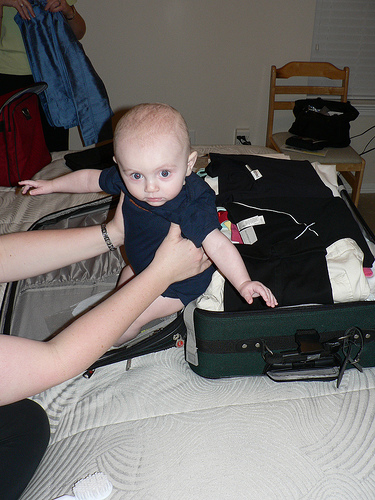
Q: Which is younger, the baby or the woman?
A: The baby is younger than the woman.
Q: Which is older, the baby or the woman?
A: The woman is older than the baby.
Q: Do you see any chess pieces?
A: No, there are no chess pieces.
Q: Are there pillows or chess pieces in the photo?
A: No, there are no chess pieces or pillows.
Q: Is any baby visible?
A: Yes, there is a baby.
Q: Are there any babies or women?
A: Yes, there is a baby.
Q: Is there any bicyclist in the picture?
A: No, there are no cyclists.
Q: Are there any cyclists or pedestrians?
A: No, there are no cyclists or pedestrians.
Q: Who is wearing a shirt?
A: The baby is wearing a shirt.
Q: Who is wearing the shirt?
A: The baby is wearing a shirt.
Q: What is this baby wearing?
A: The baby is wearing a shirt.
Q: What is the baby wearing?
A: The baby is wearing a shirt.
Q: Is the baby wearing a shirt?
A: Yes, the baby is wearing a shirt.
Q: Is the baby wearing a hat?
A: No, the baby is wearing a shirt.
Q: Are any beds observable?
A: Yes, there is a bed.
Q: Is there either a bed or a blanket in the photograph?
A: Yes, there is a bed.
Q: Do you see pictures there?
A: No, there are no pictures.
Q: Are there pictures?
A: No, there are no pictures.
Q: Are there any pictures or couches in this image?
A: No, there are no pictures or couches.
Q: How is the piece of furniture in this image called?
A: The piece of furniture is a bed.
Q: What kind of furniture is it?
A: The piece of furniture is a bed.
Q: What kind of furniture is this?
A: This is a bed.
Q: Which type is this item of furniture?
A: This is a bed.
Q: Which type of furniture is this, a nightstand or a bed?
A: This is a bed.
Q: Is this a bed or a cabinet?
A: This is a bed.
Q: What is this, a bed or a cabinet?
A: This is a bed.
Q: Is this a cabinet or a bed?
A: This is a bed.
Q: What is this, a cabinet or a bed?
A: This is a bed.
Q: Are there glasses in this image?
A: No, there are no glasses.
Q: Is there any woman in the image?
A: Yes, there is a woman.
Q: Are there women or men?
A: Yes, there is a woman.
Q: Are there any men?
A: No, there are no men.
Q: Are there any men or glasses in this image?
A: No, there are no men or glasses.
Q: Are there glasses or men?
A: No, there are no men or glasses.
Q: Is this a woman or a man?
A: This is a woman.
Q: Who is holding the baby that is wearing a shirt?
A: The woman is holding the baby.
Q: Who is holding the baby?
A: The woman is holding the baby.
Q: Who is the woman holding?
A: The woman is holding the baby.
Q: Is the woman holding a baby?
A: Yes, the woman is holding a baby.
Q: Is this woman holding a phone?
A: No, the woman is holding a baby.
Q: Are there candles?
A: No, there are no candles.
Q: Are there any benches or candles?
A: No, there are no candles or benches.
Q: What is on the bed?
A: The brush is on the bed.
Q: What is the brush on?
A: The brush is on the bed.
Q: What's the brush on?
A: The brush is on the bed.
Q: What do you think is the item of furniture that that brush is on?
A: The piece of furniture is a bed.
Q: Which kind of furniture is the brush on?
A: The brush is on the bed.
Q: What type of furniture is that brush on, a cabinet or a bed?
A: The brush is on a bed.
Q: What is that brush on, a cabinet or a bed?
A: The brush is on a bed.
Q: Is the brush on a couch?
A: No, the brush is on the bed.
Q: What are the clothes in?
A: The clothes are in the suitcase.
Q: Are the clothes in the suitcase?
A: Yes, the clothes are in the suitcase.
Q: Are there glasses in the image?
A: No, there are no glasses.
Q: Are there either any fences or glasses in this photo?
A: No, there are no glasses or fences.